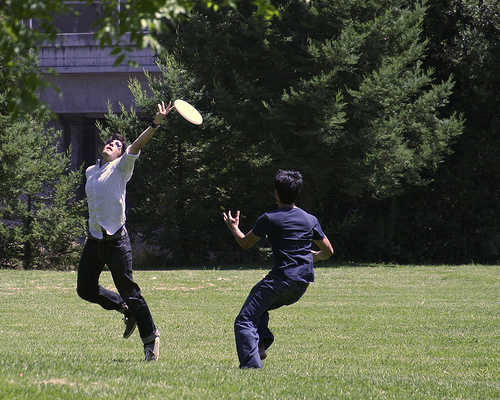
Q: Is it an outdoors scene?
A: Yes, it is outdoors.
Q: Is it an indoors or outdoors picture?
A: It is outdoors.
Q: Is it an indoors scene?
A: No, it is outdoors.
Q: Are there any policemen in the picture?
A: No, there are no policemen.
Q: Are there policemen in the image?
A: No, there are no policemen.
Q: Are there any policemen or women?
A: No, there are no policemen or women.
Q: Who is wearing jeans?
A: The man is wearing jeans.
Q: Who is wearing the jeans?
A: The man is wearing jeans.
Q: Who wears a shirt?
A: The man wears a shirt.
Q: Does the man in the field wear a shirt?
A: Yes, the man wears a shirt.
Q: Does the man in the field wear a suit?
A: No, the man wears a shirt.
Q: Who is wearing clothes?
A: The man is wearing clothes.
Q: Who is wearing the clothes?
A: The man is wearing clothes.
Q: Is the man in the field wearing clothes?
A: Yes, the man is wearing clothes.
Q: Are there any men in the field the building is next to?
A: Yes, there is a man in the field.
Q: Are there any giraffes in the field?
A: No, there is a man in the field.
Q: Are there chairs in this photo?
A: No, there are no chairs.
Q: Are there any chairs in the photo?
A: No, there are no chairs.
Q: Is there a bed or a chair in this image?
A: No, there are no chairs or beds.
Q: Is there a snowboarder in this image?
A: No, there are no snowboarders.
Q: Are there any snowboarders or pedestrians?
A: No, there are no snowboarders or pedestrians.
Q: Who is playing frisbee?
A: The man is playing frisbee.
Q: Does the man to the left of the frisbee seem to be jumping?
A: Yes, the man is jumping.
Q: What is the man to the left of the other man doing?
A: The man is jumping.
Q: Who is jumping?
A: The man is jumping.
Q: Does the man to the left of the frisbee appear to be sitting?
A: No, the man is jumping.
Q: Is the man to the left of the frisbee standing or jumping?
A: The man is jumping.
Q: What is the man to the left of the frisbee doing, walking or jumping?
A: The man is jumping.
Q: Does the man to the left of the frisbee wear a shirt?
A: Yes, the man wears a shirt.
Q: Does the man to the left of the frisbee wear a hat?
A: No, the man wears a shirt.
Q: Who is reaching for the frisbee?
A: The man is reaching for the frisbee.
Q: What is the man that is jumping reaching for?
A: The man is reaching for the frisbee.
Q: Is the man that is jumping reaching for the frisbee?
A: Yes, the man is reaching for the frisbee.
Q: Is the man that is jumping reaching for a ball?
A: No, the man is reaching for the frisbee.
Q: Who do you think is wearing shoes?
A: The man is wearing shoes.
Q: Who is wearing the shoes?
A: The man is wearing shoes.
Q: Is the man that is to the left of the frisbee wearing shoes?
A: Yes, the man is wearing shoes.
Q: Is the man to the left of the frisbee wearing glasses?
A: No, the man is wearing shoes.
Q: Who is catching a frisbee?
A: The man is catching a frisbee.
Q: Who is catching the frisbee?
A: The man is catching a frisbee.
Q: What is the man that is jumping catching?
A: The man is catching a frisbee.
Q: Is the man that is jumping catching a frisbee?
A: Yes, the man is catching a frisbee.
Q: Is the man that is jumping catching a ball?
A: No, the man is catching a frisbee.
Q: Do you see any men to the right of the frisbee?
A: No, the man is to the left of the frisbee.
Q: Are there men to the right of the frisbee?
A: No, the man is to the left of the frisbee.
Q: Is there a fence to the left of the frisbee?
A: No, there is a man to the left of the frisbee.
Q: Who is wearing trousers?
A: The man is wearing trousers.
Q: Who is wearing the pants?
A: The man is wearing trousers.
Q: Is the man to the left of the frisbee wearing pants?
A: Yes, the man is wearing pants.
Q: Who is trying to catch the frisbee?
A: The man is trying to catch the frisbee.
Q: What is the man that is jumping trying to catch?
A: The man is trying to catch the frisbee.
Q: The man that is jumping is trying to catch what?
A: The man is trying to catch the frisbee.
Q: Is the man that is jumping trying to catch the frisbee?
A: Yes, the man is trying to catch the frisbee.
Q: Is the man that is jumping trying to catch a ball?
A: No, the man is trying to catch the frisbee.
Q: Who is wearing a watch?
A: The man is wearing a watch.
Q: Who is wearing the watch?
A: The man is wearing a watch.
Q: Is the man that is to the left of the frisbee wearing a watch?
A: Yes, the man is wearing a watch.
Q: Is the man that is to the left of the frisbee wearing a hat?
A: No, the man is wearing a watch.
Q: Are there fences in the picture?
A: No, there are no fences.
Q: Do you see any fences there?
A: No, there are no fences.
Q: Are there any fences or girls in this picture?
A: No, there are no fences or girls.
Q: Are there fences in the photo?
A: No, there are no fences.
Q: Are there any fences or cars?
A: No, there are no fences or cars.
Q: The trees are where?
A: The trees are in the field.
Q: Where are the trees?
A: The trees are in the field.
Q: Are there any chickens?
A: No, there are no chickens.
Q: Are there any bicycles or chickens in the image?
A: No, there are no chickens or bicycles.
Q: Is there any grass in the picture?
A: Yes, there is grass.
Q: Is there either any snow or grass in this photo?
A: Yes, there is grass.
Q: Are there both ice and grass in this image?
A: No, there is grass but no ice.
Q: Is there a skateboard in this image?
A: No, there are no skateboards.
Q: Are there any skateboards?
A: No, there are no skateboards.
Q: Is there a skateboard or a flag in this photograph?
A: No, there are no skateboards or flags.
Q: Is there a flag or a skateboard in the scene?
A: No, there are no skateboards or flags.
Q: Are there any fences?
A: No, there are no fences.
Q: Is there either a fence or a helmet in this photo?
A: No, there are no fences or helmets.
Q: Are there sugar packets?
A: No, there are no sugar packets.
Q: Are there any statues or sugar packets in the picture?
A: No, there are no sugar packets or statues.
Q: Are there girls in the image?
A: No, there are no girls.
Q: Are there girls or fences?
A: No, there are no girls or fences.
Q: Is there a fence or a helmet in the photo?
A: No, there are no fences or helmets.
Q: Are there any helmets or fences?
A: No, there are no fences or helmets.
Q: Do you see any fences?
A: No, there are no fences.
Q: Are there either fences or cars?
A: No, there are no fences or cars.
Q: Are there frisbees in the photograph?
A: Yes, there is a frisbee.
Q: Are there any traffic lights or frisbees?
A: Yes, there is a frisbee.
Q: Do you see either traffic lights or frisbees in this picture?
A: Yes, there is a frisbee.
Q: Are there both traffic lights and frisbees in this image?
A: No, there is a frisbee but no traffic lights.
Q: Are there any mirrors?
A: No, there are no mirrors.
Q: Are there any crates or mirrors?
A: No, there are no mirrors or crates.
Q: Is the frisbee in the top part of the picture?
A: Yes, the frisbee is in the top of the image.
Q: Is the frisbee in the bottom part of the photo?
A: No, the frisbee is in the top of the image.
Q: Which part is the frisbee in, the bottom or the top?
A: The frisbee is in the top of the image.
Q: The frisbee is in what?
A: The frisbee is in the air.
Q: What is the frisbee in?
A: The frisbee is in the air.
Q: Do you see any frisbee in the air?
A: Yes, there is a frisbee in the air.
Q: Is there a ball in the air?
A: No, there is a frisbee in the air.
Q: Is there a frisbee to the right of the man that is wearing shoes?
A: Yes, there is a frisbee to the right of the man.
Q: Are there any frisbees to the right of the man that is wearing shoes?
A: Yes, there is a frisbee to the right of the man.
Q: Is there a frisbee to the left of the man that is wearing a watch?
A: No, the frisbee is to the right of the man.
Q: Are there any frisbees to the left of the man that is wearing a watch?
A: No, the frisbee is to the right of the man.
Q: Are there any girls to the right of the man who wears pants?
A: No, there is a frisbee to the right of the man.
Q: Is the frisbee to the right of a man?
A: Yes, the frisbee is to the right of a man.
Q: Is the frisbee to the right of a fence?
A: No, the frisbee is to the right of a man.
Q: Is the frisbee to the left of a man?
A: No, the frisbee is to the right of a man.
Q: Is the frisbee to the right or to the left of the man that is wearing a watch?
A: The frisbee is to the right of the man.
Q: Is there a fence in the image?
A: No, there are no fences.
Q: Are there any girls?
A: No, there are no girls.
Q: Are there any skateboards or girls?
A: No, there are no girls or skateboards.